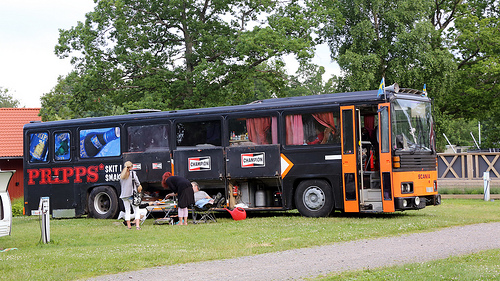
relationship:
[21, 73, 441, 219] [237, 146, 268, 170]
bus with advertising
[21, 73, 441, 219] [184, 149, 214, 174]
bus with advertising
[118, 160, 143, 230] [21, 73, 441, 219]
person standing near bus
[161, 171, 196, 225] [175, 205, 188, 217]
female with pants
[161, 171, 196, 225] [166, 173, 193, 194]
female with shirt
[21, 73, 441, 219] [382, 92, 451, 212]
bus has end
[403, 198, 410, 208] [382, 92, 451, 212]
lighting on end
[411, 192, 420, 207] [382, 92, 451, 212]
lighting on end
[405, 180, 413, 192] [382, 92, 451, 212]
lighting on end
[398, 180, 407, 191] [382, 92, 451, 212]
lighting on end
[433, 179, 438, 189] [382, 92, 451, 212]
lighting on end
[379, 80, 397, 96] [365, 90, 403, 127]
horn mounted on corner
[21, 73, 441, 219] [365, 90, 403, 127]
bus has corner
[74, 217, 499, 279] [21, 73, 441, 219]
pathway in front of bus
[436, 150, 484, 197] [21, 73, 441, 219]
fencing next to bus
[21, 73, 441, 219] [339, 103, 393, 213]
bus has doors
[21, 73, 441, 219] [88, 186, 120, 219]
bus has tire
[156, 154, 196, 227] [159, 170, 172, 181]
female with hair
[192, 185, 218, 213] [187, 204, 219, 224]
person on chair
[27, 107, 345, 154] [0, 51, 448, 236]
windows on bus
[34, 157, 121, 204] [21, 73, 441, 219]
sign on bus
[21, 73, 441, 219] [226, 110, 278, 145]
bus has window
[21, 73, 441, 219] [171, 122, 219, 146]
bus has window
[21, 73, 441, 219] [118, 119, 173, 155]
bus has window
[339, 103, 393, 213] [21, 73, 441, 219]
doors on bus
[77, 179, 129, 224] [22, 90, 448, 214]
tire for bus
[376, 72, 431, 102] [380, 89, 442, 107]
flags on top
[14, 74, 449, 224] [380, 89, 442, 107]
bus has top